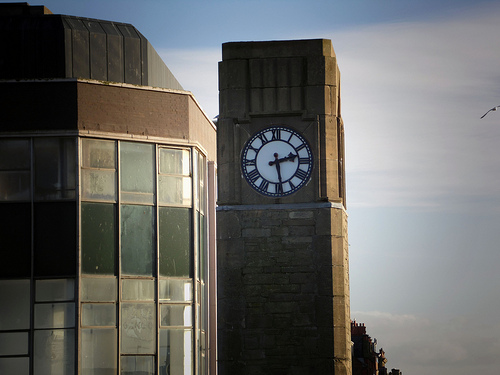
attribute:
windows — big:
[9, 283, 191, 367]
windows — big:
[4, 135, 195, 197]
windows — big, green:
[3, 198, 203, 278]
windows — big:
[2, 135, 202, 203]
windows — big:
[4, 279, 202, 371]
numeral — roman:
[268, 125, 285, 142]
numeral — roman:
[285, 130, 298, 144]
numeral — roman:
[291, 139, 307, 155]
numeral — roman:
[291, 152, 311, 165]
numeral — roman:
[293, 166, 310, 183]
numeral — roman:
[285, 174, 301, 190]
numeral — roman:
[266, 177, 286, 198]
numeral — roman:
[257, 177, 271, 194]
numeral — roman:
[242, 166, 263, 186]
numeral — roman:
[242, 155, 257, 168]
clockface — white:
[241, 123, 314, 201]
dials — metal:
[268, 144, 296, 184]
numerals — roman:
[255, 130, 267, 146]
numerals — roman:
[245, 142, 260, 157]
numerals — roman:
[239, 156, 254, 168]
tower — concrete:
[212, 32, 355, 373]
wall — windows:
[4, 128, 214, 371]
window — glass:
[118, 137, 156, 210]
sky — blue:
[26, 0, 497, 370]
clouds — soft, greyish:
[154, 13, 490, 217]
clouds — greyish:
[351, 305, 498, 374]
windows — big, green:
[193, 283, 211, 373]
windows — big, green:
[81, 199, 121, 279]